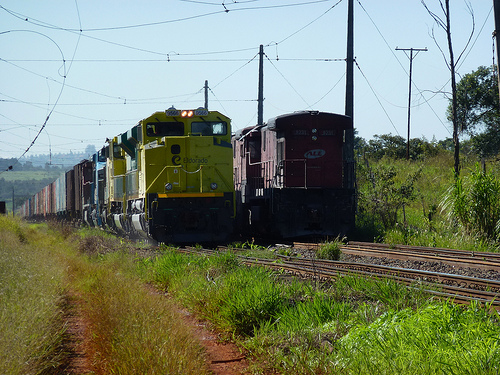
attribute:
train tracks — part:
[181, 234, 498, 311]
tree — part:
[441, 9, 464, 203]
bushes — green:
[367, 324, 473, 373]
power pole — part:
[252, 42, 267, 128]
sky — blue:
[1, 0, 498, 162]